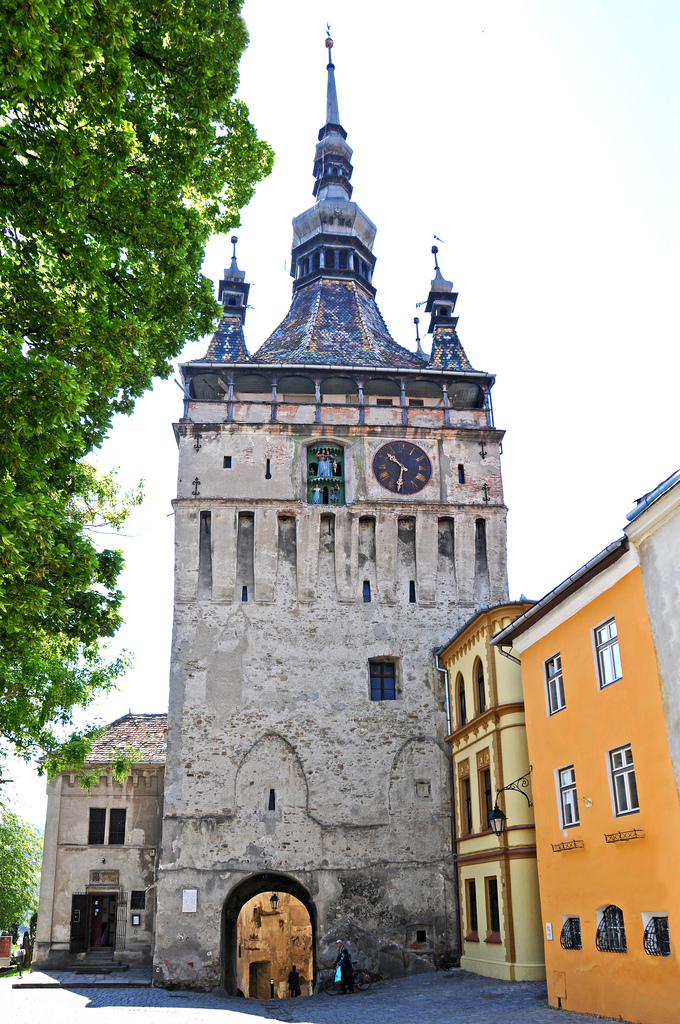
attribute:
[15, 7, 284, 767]
leaves — green 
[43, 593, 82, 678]
leaves — green 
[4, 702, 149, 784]
leaves — green 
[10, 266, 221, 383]
leaves — green 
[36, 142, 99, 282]
leaves — green 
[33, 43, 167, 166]
leaves — green 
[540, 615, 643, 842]
windows — white 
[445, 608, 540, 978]
building — yellowcake 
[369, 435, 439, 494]
clock — dark , round 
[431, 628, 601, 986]
building — yellow